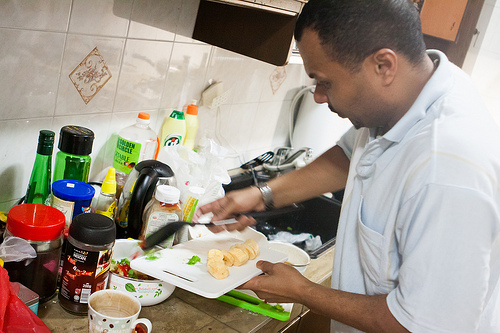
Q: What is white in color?
A: The plate.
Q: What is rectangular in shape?
A: The plate.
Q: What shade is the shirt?
A: White.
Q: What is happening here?
A: There's a man putting things into a bowl.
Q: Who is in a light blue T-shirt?
A: A man.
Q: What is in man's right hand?
A: Black spatula.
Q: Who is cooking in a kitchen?
A: A man.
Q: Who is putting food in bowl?
A: A man.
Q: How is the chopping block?
A: White plastic.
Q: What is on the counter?
A: On counter.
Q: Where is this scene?
A: Kitchen.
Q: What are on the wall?
A: Tiles.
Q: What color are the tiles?
A: White.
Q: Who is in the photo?
A: A man.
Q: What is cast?
A: Reflection.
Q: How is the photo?
A: Clear.